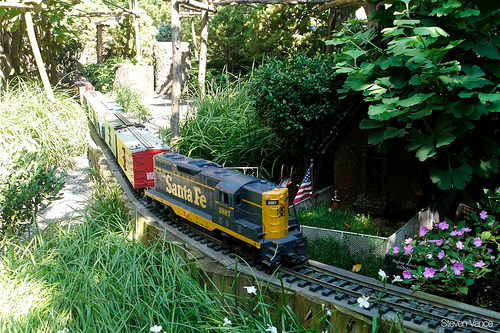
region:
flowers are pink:
[384, 205, 499, 287]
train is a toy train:
[70, 68, 316, 278]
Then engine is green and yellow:
[145, 147, 318, 276]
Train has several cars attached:
[67, 70, 315, 278]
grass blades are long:
[52, 179, 204, 331]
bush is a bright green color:
[330, 0, 499, 193]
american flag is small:
[290, 157, 323, 212]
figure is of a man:
[325, 184, 345, 212]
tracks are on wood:
[296, 259, 491, 331]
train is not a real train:
[71, 70, 313, 272]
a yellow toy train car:
[156, 145, 308, 261]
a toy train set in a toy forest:
[57, 68, 487, 326]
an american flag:
[292, 158, 319, 222]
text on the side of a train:
[156, 173, 213, 208]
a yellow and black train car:
[148, 145, 309, 266]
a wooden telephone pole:
[167, 0, 224, 150]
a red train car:
[112, 123, 162, 181]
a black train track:
[296, 265, 496, 330]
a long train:
[73, 67, 316, 266]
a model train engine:
[144, 147, 312, 280]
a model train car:
[110, 127, 174, 189]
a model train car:
[81, 84, 113, 120]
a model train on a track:
[65, 72, 316, 284]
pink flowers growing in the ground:
[380, 207, 499, 300]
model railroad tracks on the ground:
[299, 259, 495, 329]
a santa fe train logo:
[159, 174, 211, 213]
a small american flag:
[285, 166, 323, 216]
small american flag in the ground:
[293, 163, 315, 219]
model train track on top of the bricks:
[291, 256, 423, 314]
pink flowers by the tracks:
[407, 227, 474, 284]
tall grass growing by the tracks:
[82, 235, 178, 312]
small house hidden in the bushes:
[320, 94, 417, 206]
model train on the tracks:
[78, 88, 308, 265]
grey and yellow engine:
[149, 160, 308, 255]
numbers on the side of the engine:
[209, 198, 231, 220]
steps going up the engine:
[258, 243, 279, 267]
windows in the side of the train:
[215, 188, 230, 203]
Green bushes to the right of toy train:
[288, 17, 469, 117]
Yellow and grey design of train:
[154, 153, 291, 240]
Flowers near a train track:
[409, 223, 490, 290]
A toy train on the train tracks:
[71, 83, 308, 259]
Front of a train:
[263, 189, 288, 240]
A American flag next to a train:
[296, 162, 317, 202]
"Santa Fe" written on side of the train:
[160, 173, 209, 209]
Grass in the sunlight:
[11, 99, 66, 160]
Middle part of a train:
[83, 90, 160, 167]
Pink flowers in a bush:
[411, 227, 489, 288]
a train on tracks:
[59, 73, 464, 331]